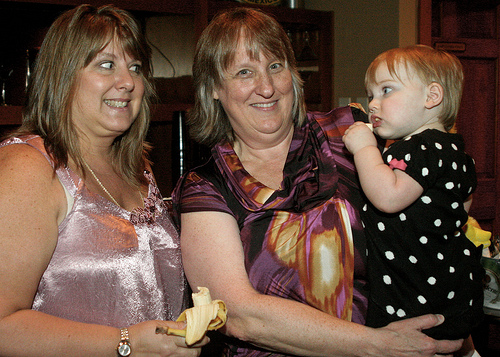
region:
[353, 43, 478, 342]
this is a baby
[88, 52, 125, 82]
this is an eye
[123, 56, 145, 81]
this is an eye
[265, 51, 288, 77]
this is an eye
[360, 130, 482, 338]
The polka dots on the child's dress.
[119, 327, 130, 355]
The watch on the woman's wrist.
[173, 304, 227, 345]
The peel of the banana.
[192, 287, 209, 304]
The half eaten banana.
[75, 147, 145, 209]
The necklace the woman is wearing.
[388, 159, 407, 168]
The pink bow on the child's dress sleeve.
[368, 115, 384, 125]
The mouth of the child.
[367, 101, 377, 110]
The nose of the child.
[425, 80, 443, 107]
The ear of the child.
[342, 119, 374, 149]
The child's hand that is holding the banana.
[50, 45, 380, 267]
there are two ladies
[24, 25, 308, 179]
the woman has brown hair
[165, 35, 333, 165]
the woman has gray hair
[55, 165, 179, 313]
the woman has a shiny shirt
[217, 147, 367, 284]
the woman has a multicolored shirt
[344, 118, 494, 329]
the baby has a polka dot shirt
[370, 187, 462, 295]
the shirt is white and black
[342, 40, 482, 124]
the baby is blonde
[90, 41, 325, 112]
the ladies eyes are blue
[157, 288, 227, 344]
a partially eaten banana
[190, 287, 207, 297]
a bitten into banana top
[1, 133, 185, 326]
a shiny pink silk blouse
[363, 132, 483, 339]
a black and white polka dot dress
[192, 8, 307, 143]
blonde hair on a woman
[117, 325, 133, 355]
a watch on a woman's wrist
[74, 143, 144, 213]
a silver chain necklace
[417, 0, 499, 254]
a brown wooden door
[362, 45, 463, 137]
the side of a tow haired baby's face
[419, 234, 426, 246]
a white polka dot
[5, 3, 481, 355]
the baby and the young woman are looking at each other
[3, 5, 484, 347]
young woman is making a fun face for the baby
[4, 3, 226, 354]
the person is holding a half eaten banan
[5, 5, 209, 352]
the lady is wearing a sleeveless dress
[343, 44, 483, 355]
the baby is holding banana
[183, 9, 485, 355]
the old woman is holding the baby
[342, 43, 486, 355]
the baby is wearing black dress with white dots in it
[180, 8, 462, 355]
the woman is smiling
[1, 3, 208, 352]
the lady is wearing a wrist watch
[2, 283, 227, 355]
half eaten banana in the hand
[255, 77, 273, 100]
The nose of the older woman.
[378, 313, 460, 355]
The hand of the older woman.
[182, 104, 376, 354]
The older woman's blouse.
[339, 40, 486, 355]
baby in a polka dotted dress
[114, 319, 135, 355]
watch on a woman's arm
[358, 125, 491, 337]
black outfit with red polka dots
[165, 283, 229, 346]
white banana with a bite taken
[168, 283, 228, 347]
banana inside a yellow banana peel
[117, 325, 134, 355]
gold wrist watch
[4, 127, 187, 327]
shimmery pink top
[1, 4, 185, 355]
woman wearing a shiny pink top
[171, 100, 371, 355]
purple black and tan top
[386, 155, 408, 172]
small pink bow on a child's sleeve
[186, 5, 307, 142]
light brown hair with bangs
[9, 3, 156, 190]
long light brown hair with bangs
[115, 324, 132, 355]
rose gold watch on right wrist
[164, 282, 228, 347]
woman holds peeled, half-eaten yellow banana